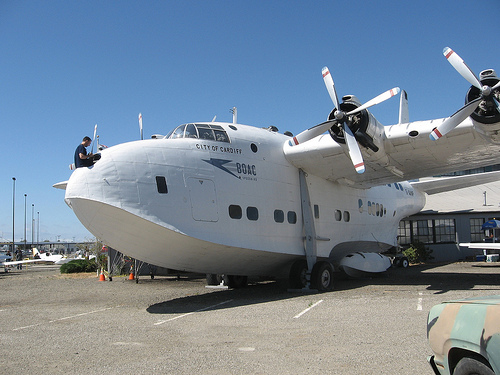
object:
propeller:
[439, 47, 482, 91]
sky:
[0, 1, 499, 46]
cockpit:
[163, 122, 231, 143]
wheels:
[289, 258, 335, 292]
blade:
[320, 66, 339, 112]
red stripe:
[322, 70, 329, 77]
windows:
[395, 214, 455, 245]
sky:
[0, 2, 499, 69]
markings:
[12, 304, 121, 333]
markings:
[154, 298, 233, 326]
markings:
[289, 298, 326, 320]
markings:
[416, 293, 423, 311]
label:
[201, 157, 258, 181]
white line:
[10, 301, 129, 333]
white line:
[151, 293, 236, 326]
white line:
[289, 295, 327, 320]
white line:
[414, 285, 424, 314]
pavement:
[1, 262, 499, 374]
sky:
[28, 12, 495, 122]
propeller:
[426, 94, 483, 143]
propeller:
[286, 117, 339, 148]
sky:
[5, 5, 498, 262]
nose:
[63, 139, 140, 231]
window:
[209, 124, 230, 143]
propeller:
[344, 85, 399, 116]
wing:
[282, 115, 498, 188]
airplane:
[51, 46, 499, 293]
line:
[293, 136, 299, 144]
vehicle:
[401, 294, 484, 374]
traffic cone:
[98, 266, 106, 281]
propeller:
[340, 119, 365, 174]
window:
[246, 206, 259, 220]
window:
[194, 124, 214, 140]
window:
[183, 124, 198, 140]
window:
[171, 124, 185, 139]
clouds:
[23, 167, 58, 216]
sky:
[79, 27, 239, 113]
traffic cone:
[129, 265, 134, 280]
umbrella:
[480, 219, 499, 230]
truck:
[424, 294, 500, 374]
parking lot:
[0, 248, 499, 373]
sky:
[1, 0, 494, 73]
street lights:
[11, 176, 16, 260]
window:
[227, 204, 242, 220]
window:
[314, 205, 320, 218]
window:
[274, 209, 285, 224]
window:
[287, 210, 297, 224]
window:
[334, 209, 342, 221]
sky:
[32, 19, 382, 79]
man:
[74, 136, 94, 168]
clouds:
[2, 2, 498, 39]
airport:
[0, 46, 499, 374]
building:
[396, 169, 499, 264]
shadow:
[146, 265, 498, 315]